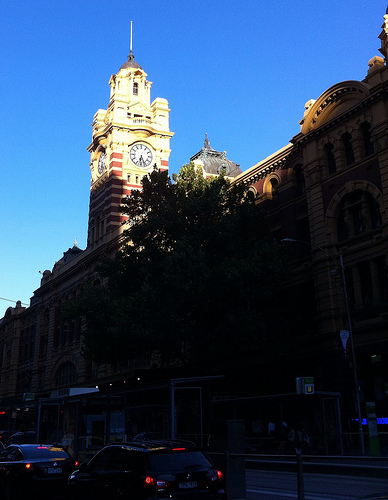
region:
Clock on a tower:
[122, 140, 156, 167]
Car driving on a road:
[64, 436, 224, 499]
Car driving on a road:
[2, 442, 81, 492]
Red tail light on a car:
[141, 475, 155, 484]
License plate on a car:
[179, 476, 200, 489]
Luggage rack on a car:
[112, 437, 194, 450]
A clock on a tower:
[129, 141, 155, 169]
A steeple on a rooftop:
[105, 20, 152, 105]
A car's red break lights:
[138, 446, 223, 483]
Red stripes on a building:
[90, 152, 169, 242]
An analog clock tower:
[90, 97, 172, 184]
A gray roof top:
[190, 133, 244, 177]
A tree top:
[121, 169, 261, 344]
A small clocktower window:
[132, 81, 139, 97]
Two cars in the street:
[0, 439, 222, 499]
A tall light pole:
[281, 232, 364, 457]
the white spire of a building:
[128, 17, 135, 56]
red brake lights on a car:
[143, 470, 223, 485]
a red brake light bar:
[171, 445, 187, 451]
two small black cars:
[0, 443, 222, 496]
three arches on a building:
[321, 126, 375, 170]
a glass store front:
[40, 403, 194, 447]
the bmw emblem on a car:
[51, 460, 57, 466]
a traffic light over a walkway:
[296, 377, 314, 393]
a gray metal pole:
[169, 388, 175, 442]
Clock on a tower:
[127, 134, 162, 176]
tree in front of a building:
[137, 171, 290, 379]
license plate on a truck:
[175, 480, 205, 488]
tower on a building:
[80, 42, 168, 243]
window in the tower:
[131, 77, 143, 96]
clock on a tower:
[124, 137, 159, 171]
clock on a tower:
[120, 133, 161, 170]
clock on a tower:
[123, 129, 160, 173]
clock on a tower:
[123, 133, 156, 170]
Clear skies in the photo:
[219, 51, 256, 101]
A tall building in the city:
[91, 41, 179, 191]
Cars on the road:
[5, 423, 215, 497]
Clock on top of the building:
[128, 144, 159, 171]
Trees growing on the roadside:
[155, 203, 240, 333]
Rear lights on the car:
[130, 468, 228, 492]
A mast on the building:
[124, 15, 142, 56]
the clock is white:
[127, 139, 158, 172]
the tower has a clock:
[78, 10, 171, 236]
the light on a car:
[150, 439, 191, 458]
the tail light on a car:
[139, 470, 155, 493]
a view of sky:
[189, 38, 235, 95]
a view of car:
[66, 433, 224, 499]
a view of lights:
[131, 461, 161, 494]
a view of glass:
[135, 432, 219, 483]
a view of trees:
[83, 265, 273, 421]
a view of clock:
[123, 128, 176, 171]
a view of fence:
[259, 460, 299, 476]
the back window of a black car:
[138, 441, 214, 481]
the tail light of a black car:
[141, 473, 160, 491]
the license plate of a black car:
[177, 480, 209, 494]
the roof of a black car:
[111, 434, 179, 461]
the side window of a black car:
[85, 447, 141, 478]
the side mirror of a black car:
[67, 457, 86, 471]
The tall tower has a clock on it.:
[124, 141, 151, 175]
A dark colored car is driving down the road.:
[69, 446, 232, 496]